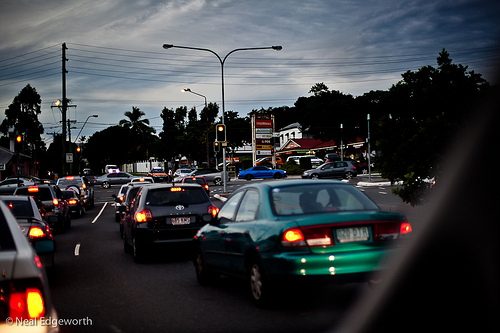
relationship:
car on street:
[190, 175, 412, 302] [9, 172, 330, 331]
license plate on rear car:
[333, 226, 378, 240] [183, 164, 415, 304]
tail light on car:
[80, 183, 97, 195] [46, 164, 100, 206]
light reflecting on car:
[328, 250, 337, 260] [190, 175, 412, 302]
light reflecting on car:
[327, 265, 333, 273] [190, 175, 412, 302]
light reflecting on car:
[298, 255, 305, 265] [190, 175, 412, 302]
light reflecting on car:
[300, 265, 306, 274] [190, 175, 412, 302]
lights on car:
[281, 226, 306, 246] [190, 175, 412, 302]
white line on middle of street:
[86, 195, 114, 236] [26, 178, 458, 329]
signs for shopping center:
[252, 115, 276, 152] [212, 117, 375, 179]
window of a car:
[144, 187, 211, 207] [120, 182, 220, 262]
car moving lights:
[190, 175, 412, 302] [398, 221, 412, 235]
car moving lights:
[2, 191, 56, 267] [27, 227, 48, 242]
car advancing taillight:
[120, 182, 220, 262] [135, 212, 145, 223]